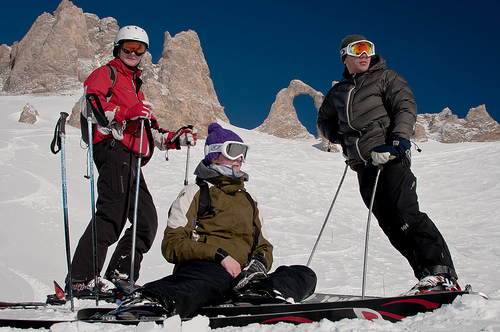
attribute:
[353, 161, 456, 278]
pants — black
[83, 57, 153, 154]
jacket — red 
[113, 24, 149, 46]
helmet — white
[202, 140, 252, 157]
goggles — white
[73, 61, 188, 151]
jacket — red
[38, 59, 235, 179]
jacket — red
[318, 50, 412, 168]
jacket — brown, white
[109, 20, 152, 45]
helmet — white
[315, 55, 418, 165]
jacket — grey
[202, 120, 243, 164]
beanie — purple